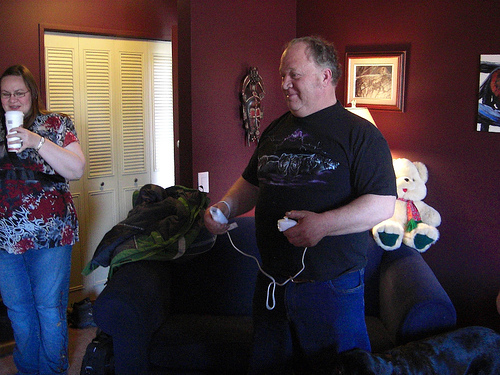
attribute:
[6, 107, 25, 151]
cup — white , disposable 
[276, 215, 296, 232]
nunchuk — white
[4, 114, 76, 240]
shirt — white, black, patterned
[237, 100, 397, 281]
shirt — black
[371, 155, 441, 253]
bear — white, stuffed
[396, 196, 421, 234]
scarf — red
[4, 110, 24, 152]
cup — coffee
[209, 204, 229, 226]
remote control — white, Wii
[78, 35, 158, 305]
closet doors — white, bi-fold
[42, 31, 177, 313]
closet doors — white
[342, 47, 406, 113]
frame — wooden 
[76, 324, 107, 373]
bag — black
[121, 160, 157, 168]
slat — white, wooden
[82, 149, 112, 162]
slat — white , wooden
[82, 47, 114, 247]
door — white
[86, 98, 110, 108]
slat — wooden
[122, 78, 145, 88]
slat — white, wooden